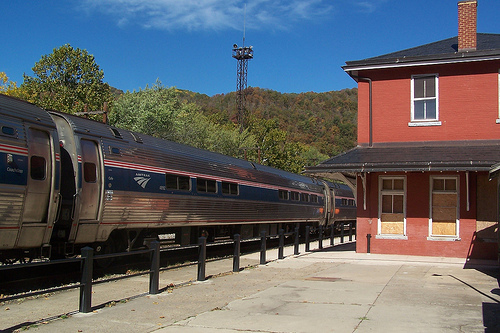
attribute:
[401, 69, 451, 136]
frame — white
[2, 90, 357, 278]
train — silver, blue, red, white, shiny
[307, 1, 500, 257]
building — red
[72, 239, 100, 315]
pole — black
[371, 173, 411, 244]
window — white, boarded up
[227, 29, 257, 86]
tower — black, metal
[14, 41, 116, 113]
tree — tall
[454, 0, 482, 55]
chimney — red, brick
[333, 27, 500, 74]
roof — black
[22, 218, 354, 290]
fence — metal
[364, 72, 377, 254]
drain — black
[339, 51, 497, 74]
gutter — brown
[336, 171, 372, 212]
corbel — white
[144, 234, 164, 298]
post — short